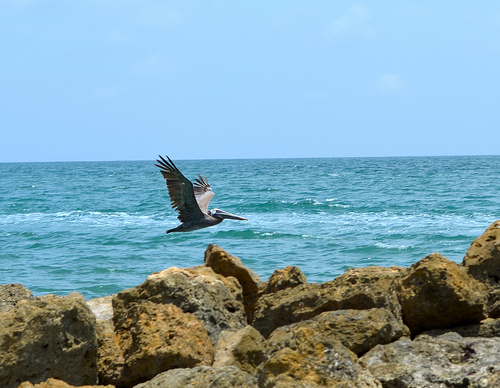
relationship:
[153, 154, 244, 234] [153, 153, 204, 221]
bird with wing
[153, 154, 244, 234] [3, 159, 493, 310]
bird flying by an ocean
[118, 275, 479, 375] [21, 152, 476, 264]
rocks by an ocean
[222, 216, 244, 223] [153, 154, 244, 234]
beak of a bird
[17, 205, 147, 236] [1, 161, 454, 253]
wave in ocean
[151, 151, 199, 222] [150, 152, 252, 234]
wing of bird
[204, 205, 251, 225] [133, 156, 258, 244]
head of bird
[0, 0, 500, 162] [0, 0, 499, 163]
cloud in blue sky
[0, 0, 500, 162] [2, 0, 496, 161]
cloud in sky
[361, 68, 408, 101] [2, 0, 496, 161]
cloud in sky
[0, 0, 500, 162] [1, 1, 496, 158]
cloud in blue sky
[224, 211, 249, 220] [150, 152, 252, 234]
beak on bird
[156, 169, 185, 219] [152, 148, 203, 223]
feathers on wing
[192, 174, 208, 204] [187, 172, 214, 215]
feathers on wing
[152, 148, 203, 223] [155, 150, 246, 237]
wing of bird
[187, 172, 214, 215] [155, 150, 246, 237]
wing of bird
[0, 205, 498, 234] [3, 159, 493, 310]
wave in ocean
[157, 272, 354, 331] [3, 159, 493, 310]
rocks in front of ocean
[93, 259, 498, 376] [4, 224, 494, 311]
rocks by sea shore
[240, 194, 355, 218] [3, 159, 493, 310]
waves in ocean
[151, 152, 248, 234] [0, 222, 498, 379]
bird above rocks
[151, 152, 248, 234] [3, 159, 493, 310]
bird near ocean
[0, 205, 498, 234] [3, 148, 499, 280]
wave in ocean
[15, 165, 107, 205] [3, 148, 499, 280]
waves in ocean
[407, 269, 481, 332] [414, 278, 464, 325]
rock covered in moss